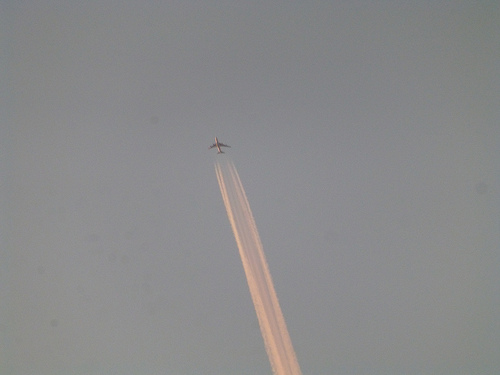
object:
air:
[2, 2, 497, 374]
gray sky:
[0, 0, 500, 169]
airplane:
[208, 136, 231, 154]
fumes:
[214, 162, 299, 373]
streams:
[214, 161, 303, 374]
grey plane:
[185, 121, 247, 188]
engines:
[209, 143, 228, 148]